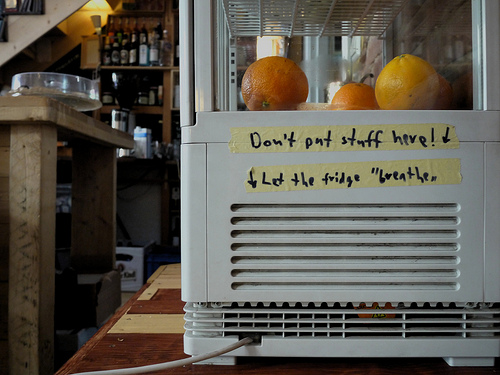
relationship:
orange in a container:
[235, 56, 312, 108] [180, 0, 499, 369]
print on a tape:
[251, 127, 456, 147] [226, 122, 460, 150]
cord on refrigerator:
[68, 335, 253, 373] [177, 0, 497, 366]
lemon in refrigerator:
[376, 59, 443, 106] [174, 5, 467, 335]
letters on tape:
[246, 128, 455, 148] [236, 114, 474, 161]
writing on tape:
[249, 167, 443, 187] [231, 139, 492, 210]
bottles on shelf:
[100, 12, 167, 65] [79, 57, 176, 76]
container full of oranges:
[180, 0, 499, 369] [233, 42, 450, 117]